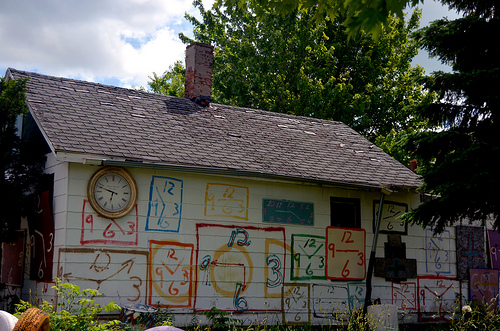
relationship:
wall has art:
[70, 161, 496, 319] [78, 167, 479, 309]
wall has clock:
[70, 161, 496, 319] [91, 159, 149, 215]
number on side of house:
[341, 231, 359, 247] [4, 65, 446, 322]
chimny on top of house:
[178, 34, 219, 105] [4, 65, 446, 322]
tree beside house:
[151, 2, 434, 144] [4, 65, 446, 322]